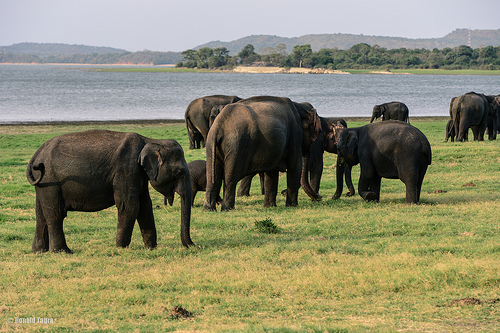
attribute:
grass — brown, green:
[2, 119, 498, 331]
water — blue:
[0, 62, 499, 124]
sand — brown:
[233, 65, 349, 73]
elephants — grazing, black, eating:
[25, 94, 497, 252]